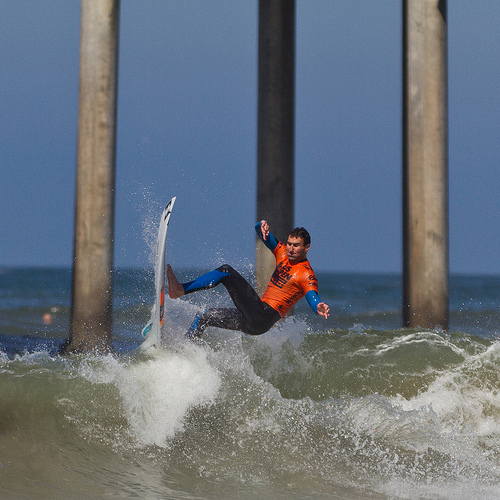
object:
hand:
[258, 218, 271, 242]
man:
[166, 218, 331, 349]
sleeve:
[307, 290, 320, 305]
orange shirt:
[259, 241, 320, 321]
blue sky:
[0, 0, 500, 275]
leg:
[182, 306, 242, 345]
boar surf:
[141, 306, 275, 452]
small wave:
[0, 340, 242, 500]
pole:
[400, 1, 452, 333]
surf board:
[141, 197, 181, 370]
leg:
[180, 263, 267, 322]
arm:
[300, 274, 321, 311]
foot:
[165, 260, 185, 299]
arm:
[254, 221, 284, 257]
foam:
[109, 357, 262, 451]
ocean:
[0, 268, 500, 498]